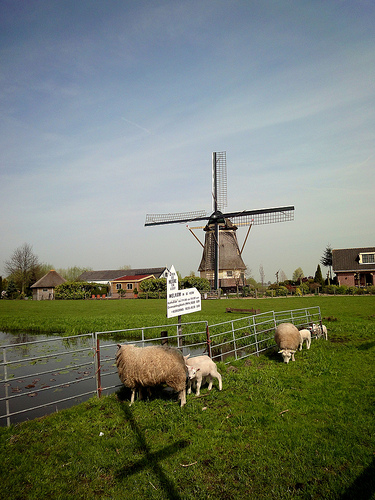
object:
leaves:
[58, 368, 69, 375]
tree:
[2, 242, 45, 298]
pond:
[0, 328, 250, 428]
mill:
[144, 149, 296, 295]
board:
[167, 265, 201, 320]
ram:
[115, 341, 189, 407]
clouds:
[52, 152, 118, 195]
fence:
[0, 306, 324, 435]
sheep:
[274, 322, 303, 365]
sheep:
[299, 329, 312, 351]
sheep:
[311, 323, 328, 341]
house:
[73, 267, 172, 297]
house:
[29, 268, 70, 300]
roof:
[331, 246, 375, 271]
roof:
[111, 275, 151, 282]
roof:
[73, 267, 166, 281]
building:
[110, 274, 157, 298]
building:
[331, 247, 374, 289]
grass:
[0, 293, 375, 500]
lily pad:
[58, 370, 69, 376]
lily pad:
[55, 357, 62, 363]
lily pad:
[28, 361, 37, 366]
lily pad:
[7, 372, 15, 379]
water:
[0, 326, 247, 432]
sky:
[0, 0, 375, 285]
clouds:
[88, 112, 172, 169]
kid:
[185, 355, 222, 397]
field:
[0, 297, 375, 500]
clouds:
[295, 124, 370, 207]